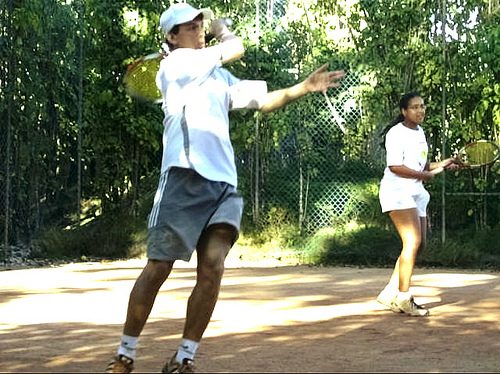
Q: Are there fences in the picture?
A: Yes, there is a fence.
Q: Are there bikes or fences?
A: Yes, there is a fence.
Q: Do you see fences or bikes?
A: Yes, there is a fence.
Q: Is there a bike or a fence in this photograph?
A: Yes, there is a fence.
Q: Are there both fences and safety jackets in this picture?
A: No, there is a fence but no safety jackets.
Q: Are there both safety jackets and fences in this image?
A: No, there is a fence but no safety jackets.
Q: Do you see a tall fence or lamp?
A: Yes, there is a tall fence.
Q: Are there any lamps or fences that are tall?
A: Yes, the fence is tall.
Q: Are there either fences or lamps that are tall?
A: Yes, the fence is tall.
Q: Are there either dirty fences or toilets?
A: Yes, there is a dirty fence.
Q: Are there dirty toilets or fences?
A: Yes, there is a dirty fence.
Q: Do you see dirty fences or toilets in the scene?
A: Yes, there is a dirty fence.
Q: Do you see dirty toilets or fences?
A: Yes, there is a dirty fence.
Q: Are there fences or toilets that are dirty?
A: Yes, the fence is dirty.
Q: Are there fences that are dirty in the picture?
A: Yes, there is a dirty fence.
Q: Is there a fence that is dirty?
A: Yes, there is a fence that is dirty.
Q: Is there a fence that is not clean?
A: Yes, there is a dirty fence.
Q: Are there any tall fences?
A: Yes, there is a tall fence.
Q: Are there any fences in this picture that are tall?
A: Yes, there is a fence that is tall.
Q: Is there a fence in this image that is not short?
A: Yes, there is a tall fence.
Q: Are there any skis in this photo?
A: No, there are no skis.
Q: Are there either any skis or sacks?
A: No, there are no skis or sacks.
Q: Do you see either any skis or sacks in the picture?
A: No, there are no skis or sacks.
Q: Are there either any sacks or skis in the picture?
A: No, there are no skis or sacks.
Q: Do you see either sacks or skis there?
A: No, there are no skis or sacks.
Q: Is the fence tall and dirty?
A: Yes, the fence is tall and dirty.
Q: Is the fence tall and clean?
A: No, the fence is tall but dirty.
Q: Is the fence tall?
A: Yes, the fence is tall.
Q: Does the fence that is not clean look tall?
A: Yes, the fence is tall.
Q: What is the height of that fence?
A: The fence is tall.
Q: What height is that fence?
A: The fence is tall.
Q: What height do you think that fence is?
A: The fence is tall.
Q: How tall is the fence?
A: The fence is tall.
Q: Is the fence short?
A: No, the fence is tall.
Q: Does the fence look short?
A: No, the fence is tall.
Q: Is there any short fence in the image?
A: No, there is a fence but it is tall.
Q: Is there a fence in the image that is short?
A: No, there is a fence but it is tall.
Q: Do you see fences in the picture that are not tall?
A: No, there is a fence but it is tall.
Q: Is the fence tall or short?
A: The fence is tall.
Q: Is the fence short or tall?
A: The fence is tall.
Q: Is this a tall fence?
A: Yes, this is a tall fence.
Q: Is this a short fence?
A: No, this is a tall fence.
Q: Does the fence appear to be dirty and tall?
A: Yes, the fence is dirty and tall.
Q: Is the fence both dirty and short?
A: No, the fence is dirty but tall.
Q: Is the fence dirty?
A: Yes, the fence is dirty.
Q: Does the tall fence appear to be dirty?
A: Yes, the fence is dirty.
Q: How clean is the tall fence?
A: The fence is dirty.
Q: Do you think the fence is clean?
A: No, the fence is dirty.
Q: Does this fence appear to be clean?
A: No, the fence is dirty.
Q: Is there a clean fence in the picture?
A: No, there is a fence but it is dirty.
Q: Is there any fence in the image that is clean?
A: No, there is a fence but it is dirty.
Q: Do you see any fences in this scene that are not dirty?
A: No, there is a fence but it is dirty.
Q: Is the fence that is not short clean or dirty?
A: The fence is dirty.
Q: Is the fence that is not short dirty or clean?
A: The fence is dirty.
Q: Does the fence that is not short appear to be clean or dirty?
A: The fence is dirty.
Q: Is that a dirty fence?
A: Yes, that is a dirty fence.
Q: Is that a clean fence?
A: No, that is a dirty fence.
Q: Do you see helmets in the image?
A: No, there are no helmets.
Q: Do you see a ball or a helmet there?
A: No, there are no helmets or balls.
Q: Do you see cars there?
A: No, there are no cars.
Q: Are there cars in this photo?
A: No, there are no cars.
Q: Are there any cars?
A: No, there are no cars.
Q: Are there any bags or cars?
A: No, there are no cars or bags.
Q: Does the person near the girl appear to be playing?
A: Yes, the person is playing.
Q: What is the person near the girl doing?
A: The person is playing.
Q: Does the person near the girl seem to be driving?
A: No, the person is playing.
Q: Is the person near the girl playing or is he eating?
A: The person is playing.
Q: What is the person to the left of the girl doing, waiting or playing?
A: The person is playing.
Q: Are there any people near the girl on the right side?
A: Yes, there is a person near the girl.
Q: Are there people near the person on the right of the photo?
A: Yes, there is a person near the girl.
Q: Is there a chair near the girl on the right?
A: No, there is a person near the girl.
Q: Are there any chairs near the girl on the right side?
A: No, there is a person near the girl.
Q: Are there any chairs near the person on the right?
A: No, there is a person near the girl.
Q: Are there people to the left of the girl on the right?
A: Yes, there is a person to the left of the girl.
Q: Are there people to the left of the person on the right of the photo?
A: Yes, there is a person to the left of the girl.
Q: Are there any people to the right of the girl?
A: No, the person is to the left of the girl.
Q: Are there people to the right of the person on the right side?
A: No, the person is to the left of the girl.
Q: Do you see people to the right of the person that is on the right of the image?
A: No, the person is to the left of the girl.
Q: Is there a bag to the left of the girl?
A: No, there is a person to the left of the girl.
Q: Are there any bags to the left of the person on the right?
A: No, there is a person to the left of the girl.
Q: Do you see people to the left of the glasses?
A: Yes, there is a person to the left of the glasses.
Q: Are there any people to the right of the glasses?
A: No, the person is to the left of the glasses.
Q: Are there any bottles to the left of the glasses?
A: No, there is a person to the left of the glasses.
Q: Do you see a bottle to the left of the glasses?
A: No, there is a person to the left of the glasses.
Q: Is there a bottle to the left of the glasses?
A: No, there is a person to the left of the glasses.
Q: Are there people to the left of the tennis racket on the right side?
A: Yes, there is a person to the left of the racket.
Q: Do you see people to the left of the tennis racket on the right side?
A: Yes, there is a person to the left of the racket.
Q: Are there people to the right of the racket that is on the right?
A: No, the person is to the left of the racket.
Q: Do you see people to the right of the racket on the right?
A: No, the person is to the left of the racket.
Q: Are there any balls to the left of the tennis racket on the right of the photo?
A: No, there is a person to the left of the racket.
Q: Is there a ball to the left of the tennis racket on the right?
A: No, there is a person to the left of the racket.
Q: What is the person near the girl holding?
A: The person is holding the racket.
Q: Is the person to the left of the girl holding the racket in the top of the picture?
A: Yes, the person is holding the tennis racket.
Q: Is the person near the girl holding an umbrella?
A: No, the person is holding the tennis racket.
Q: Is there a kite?
A: No, there are no kites.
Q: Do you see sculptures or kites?
A: No, there are no kites or sculptures.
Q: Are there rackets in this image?
A: Yes, there is a racket.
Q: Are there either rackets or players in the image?
A: Yes, there is a racket.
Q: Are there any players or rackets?
A: Yes, there is a racket.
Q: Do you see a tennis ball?
A: No, there are no tennis balls.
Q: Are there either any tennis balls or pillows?
A: No, there are no tennis balls or pillows.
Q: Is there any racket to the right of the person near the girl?
A: Yes, there is a racket to the right of the person.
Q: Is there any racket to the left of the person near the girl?
A: No, the racket is to the right of the person.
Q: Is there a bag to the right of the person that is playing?
A: No, there is a racket to the right of the person.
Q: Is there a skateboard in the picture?
A: No, there are no skateboards.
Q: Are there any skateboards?
A: No, there are no skateboards.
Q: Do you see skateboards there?
A: No, there are no skateboards.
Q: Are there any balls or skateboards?
A: No, there are no skateboards or balls.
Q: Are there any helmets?
A: No, there are no helmets.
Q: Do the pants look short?
A: Yes, the pants are short.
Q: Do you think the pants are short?
A: Yes, the pants are short.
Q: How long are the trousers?
A: The trousers are short.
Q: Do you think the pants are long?
A: No, the pants are short.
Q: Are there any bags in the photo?
A: No, there are no bags.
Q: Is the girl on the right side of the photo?
A: Yes, the girl is on the right of the image.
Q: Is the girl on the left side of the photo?
A: No, the girl is on the right of the image.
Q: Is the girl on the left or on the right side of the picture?
A: The girl is on the right of the image.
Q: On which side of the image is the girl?
A: The girl is on the right of the image.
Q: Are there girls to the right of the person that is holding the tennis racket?
A: Yes, there is a girl to the right of the person.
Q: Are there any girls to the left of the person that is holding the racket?
A: No, the girl is to the right of the person.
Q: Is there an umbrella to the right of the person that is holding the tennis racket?
A: No, there is a girl to the right of the person.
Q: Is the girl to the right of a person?
A: Yes, the girl is to the right of a person.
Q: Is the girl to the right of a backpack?
A: No, the girl is to the right of a person.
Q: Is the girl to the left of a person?
A: No, the girl is to the right of a person.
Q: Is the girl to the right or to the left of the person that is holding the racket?
A: The girl is to the right of the person.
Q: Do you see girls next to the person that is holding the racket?
A: Yes, there is a girl next to the person.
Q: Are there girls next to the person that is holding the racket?
A: Yes, there is a girl next to the person.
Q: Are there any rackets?
A: Yes, there is a racket.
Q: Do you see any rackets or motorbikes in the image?
A: Yes, there is a racket.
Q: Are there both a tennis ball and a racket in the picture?
A: No, there is a racket but no tennis balls.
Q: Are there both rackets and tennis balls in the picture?
A: No, there is a racket but no tennis balls.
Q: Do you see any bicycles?
A: No, there are no bicycles.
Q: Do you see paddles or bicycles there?
A: No, there are no bicycles or paddles.